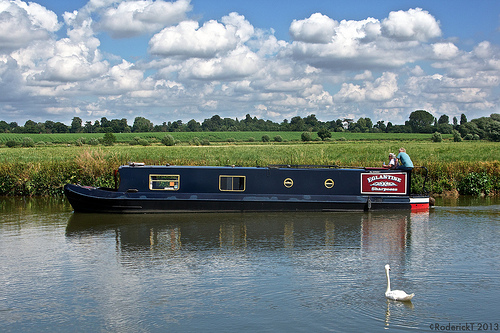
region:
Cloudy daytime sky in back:
[0, 1, 498, 126]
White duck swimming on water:
[380, 261, 415, 299]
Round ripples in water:
[298, 272, 498, 331]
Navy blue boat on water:
[58, 163, 435, 213]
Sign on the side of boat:
[360, 171, 407, 196]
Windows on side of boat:
[147, 172, 247, 192]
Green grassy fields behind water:
[1, 131, 497, 165]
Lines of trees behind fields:
[2, 111, 498, 136]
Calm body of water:
[0, 193, 498, 331]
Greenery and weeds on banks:
[1, 156, 498, 195]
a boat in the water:
[94, 101, 454, 330]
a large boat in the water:
[68, 102, 451, 257]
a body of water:
[110, 213, 296, 325]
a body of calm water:
[177, 218, 297, 325]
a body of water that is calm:
[103, 232, 326, 332]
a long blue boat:
[102, 120, 458, 295]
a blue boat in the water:
[96, 101, 490, 314]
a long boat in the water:
[77, 133, 402, 292]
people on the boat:
[329, 133, 484, 297]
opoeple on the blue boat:
[322, 140, 454, 222]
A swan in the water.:
[379, 263, 416, 305]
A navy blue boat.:
[53, 162, 417, 207]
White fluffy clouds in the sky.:
[3, 2, 485, 69]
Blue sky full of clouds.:
[9, 2, 499, 104]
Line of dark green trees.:
[2, 109, 497, 135]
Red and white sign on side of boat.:
[356, 173, 410, 194]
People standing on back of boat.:
[382, 147, 419, 195]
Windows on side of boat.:
[140, 174, 256, 192]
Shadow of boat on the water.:
[66, 214, 428, 259]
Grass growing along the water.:
[0, 159, 89, 204]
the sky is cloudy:
[42, 18, 404, 130]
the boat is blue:
[45, 159, 462, 329]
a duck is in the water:
[365, 240, 402, 291]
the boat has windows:
[125, 165, 272, 227]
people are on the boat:
[352, 147, 479, 202]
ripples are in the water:
[172, 247, 275, 305]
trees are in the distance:
[33, 115, 283, 182]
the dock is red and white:
[402, 188, 462, 268]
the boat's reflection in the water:
[27, 179, 280, 286]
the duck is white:
[346, 267, 426, 315]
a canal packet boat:
[56, 146, 433, 213]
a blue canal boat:
[62, 155, 435, 213]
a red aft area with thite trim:
[405, 188, 431, 217]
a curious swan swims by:
[384, 258, 416, 305]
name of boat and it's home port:
[362, 170, 408, 195]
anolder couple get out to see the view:
[387, 145, 414, 192]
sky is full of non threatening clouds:
[0, 3, 491, 127]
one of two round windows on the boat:
[320, 176, 337, 191]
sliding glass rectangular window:
[219, 177, 246, 189]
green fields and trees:
[10, 113, 497, 167]